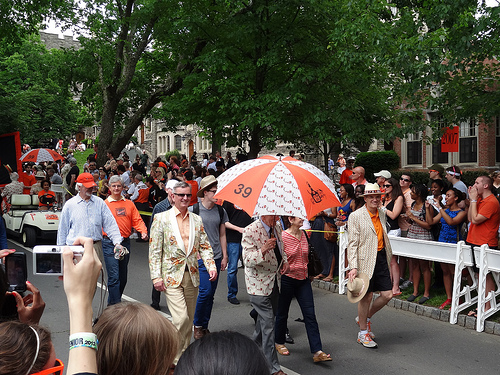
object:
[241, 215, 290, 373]
man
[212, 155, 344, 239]
umbrella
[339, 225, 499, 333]
barricade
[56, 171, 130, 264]
man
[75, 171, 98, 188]
cap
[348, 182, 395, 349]
man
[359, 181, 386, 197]
hat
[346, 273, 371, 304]
hat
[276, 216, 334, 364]
woman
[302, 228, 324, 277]
purse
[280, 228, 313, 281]
shirt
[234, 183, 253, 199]
number 39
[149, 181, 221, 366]
man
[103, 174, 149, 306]
man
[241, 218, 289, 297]
blazer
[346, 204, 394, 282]
blazer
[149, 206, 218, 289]
blazer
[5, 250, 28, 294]
smartphone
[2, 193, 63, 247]
golf cart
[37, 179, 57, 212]
woman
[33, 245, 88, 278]
camera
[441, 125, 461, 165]
sign